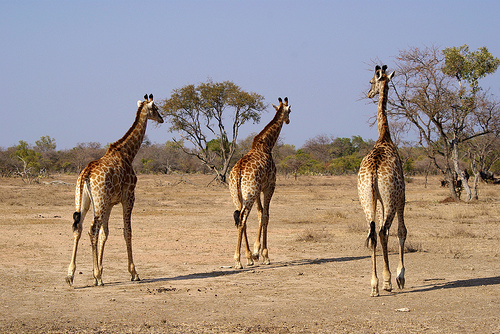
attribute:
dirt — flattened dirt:
[6, 175, 499, 326]